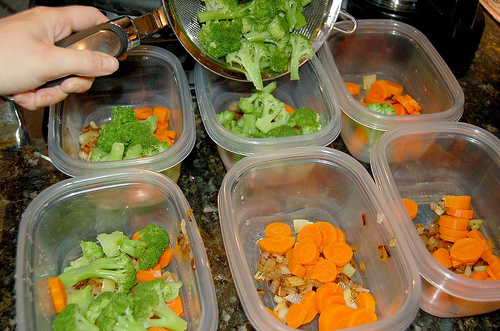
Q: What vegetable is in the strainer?
A: Broccoli.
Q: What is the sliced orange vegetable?
A: Carrots.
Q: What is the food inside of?
A: Clear plastic container.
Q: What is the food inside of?
A: Clear plastic container.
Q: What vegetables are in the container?
A: Broccoli and carrots.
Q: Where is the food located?
A: Clear plastic container.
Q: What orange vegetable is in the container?
A: Sliced carrots.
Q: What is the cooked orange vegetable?
A: Carrots.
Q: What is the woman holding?
A: A strainer.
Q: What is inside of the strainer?
A: Cooked broccoli.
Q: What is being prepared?
A: Vegetables.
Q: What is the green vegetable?
A: Broccoli.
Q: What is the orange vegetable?
A: Carrot.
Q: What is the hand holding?
A: Strainer.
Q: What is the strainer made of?
A: Metal.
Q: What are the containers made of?
A: Plastic.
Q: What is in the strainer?
A: Broccoli.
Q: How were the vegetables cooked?
A: Steamed.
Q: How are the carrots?
A: Cut.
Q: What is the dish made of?
A: Plastic.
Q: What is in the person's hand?
A: Strainer.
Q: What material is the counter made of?
A: Marble.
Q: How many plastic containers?
A: Six.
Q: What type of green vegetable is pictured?
A: Broccoli.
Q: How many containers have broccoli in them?
A: Four.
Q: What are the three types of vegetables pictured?
A: Broccoli, carrots and onions.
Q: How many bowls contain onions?
A: Six.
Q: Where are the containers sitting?
A: Counter.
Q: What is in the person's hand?
A: A strainer.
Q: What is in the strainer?
A: Broccoli.